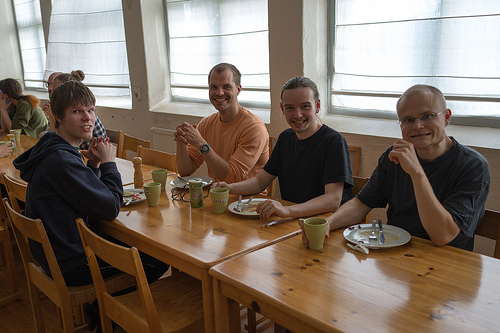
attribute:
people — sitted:
[171, 62, 490, 254]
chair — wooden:
[71, 211, 248, 331]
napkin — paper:
[340, 236, 388, 260]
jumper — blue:
[17, 140, 119, 284]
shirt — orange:
[189, 112, 263, 189]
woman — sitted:
[29, 66, 143, 243]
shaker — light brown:
[149, 179, 230, 240]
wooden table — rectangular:
[257, 250, 499, 331]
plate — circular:
[226, 196, 276, 219]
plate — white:
[341, 219, 413, 251]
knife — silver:
[264, 212, 283, 227]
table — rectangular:
[7, 131, 345, 273]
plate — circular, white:
[303, 192, 418, 261]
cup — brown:
[204, 186, 234, 218]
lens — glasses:
[402, 113, 421, 125]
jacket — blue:
[17, 128, 120, 268]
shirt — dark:
[358, 136, 491, 252]